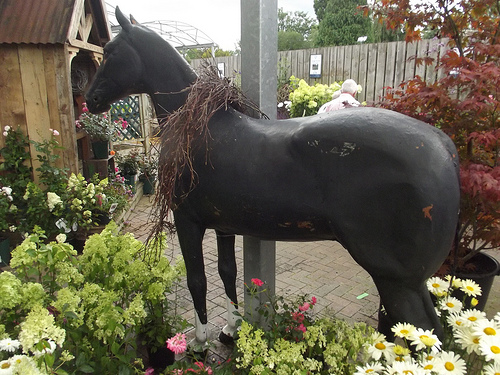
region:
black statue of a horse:
[82, 4, 463, 360]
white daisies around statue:
[0, 274, 499, 374]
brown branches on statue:
[127, 45, 270, 274]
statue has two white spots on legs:
[186, 293, 239, 353]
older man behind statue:
[314, 78, 360, 114]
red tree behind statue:
[351, 0, 498, 272]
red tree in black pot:
[377, 245, 499, 360]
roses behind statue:
[0, 102, 136, 219]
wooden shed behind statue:
[0, 0, 113, 193]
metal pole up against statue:
[240, 0, 277, 332]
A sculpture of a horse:
[204, 126, 394, 230]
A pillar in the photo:
[246, 4, 283, 132]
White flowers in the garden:
[430, 306, 497, 373]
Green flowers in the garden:
[55, 242, 133, 337]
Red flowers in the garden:
[147, 332, 214, 373]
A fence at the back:
[305, 49, 395, 89]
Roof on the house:
[24, 17, 63, 38]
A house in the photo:
[3, 17, 76, 128]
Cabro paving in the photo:
[310, 263, 350, 309]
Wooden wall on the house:
[17, 53, 75, 149]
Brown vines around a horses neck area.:
[148, 59, 268, 251]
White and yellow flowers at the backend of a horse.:
[428, 273, 498, 374]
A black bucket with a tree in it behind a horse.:
[451, 243, 499, 314]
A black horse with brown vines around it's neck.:
[83, 5, 461, 350]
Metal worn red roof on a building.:
[1, 0, 111, 46]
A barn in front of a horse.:
[2, 0, 113, 224]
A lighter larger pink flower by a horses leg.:
[163, 331, 188, 352]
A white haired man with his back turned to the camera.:
[317, 77, 359, 117]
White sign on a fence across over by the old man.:
[306, 51, 322, 76]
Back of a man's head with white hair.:
[341, 75, 357, 95]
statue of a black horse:
[70, 8, 472, 335]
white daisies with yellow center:
[357, 274, 494, 368]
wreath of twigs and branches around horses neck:
[143, 45, 255, 247]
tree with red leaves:
[419, 1, 498, 285]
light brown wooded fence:
[178, 29, 493, 91]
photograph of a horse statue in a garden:
[23, 33, 493, 362]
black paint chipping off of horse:
[395, 190, 447, 240]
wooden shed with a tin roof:
[2, 0, 110, 176]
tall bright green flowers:
[74, 220, 183, 357]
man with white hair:
[310, 68, 377, 121]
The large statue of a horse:
[82, 5, 465, 359]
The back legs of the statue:
[372, 270, 450, 355]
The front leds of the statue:
[172, 218, 242, 350]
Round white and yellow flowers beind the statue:
[352, 270, 498, 373]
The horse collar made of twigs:
[138, 57, 266, 272]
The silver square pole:
[236, 0, 283, 336]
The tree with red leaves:
[352, 3, 497, 278]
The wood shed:
[0, 2, 121, 199]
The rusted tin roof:
[0, 0, 80, 49]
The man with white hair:
[311, 75, 361, 118]